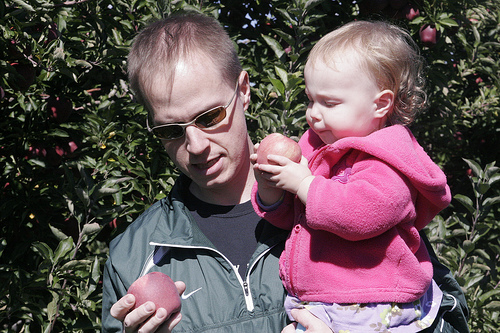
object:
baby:
[248, 22, 453, 333]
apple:
[253, 132, 304, 171]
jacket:
[241, 123, 454, 305]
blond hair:
[301, 21, 427, 128]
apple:
[124, 269, 182, 325]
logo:
[181, 285, 204, 301]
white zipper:
[233, 279, 260, 312]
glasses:
[140, 82, 237, 145]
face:
[140, 52, 245, 187]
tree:
[0, 0, 499, 333]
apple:
[50, 136, 79, 156]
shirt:
[101, 190, 468, 333]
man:
[89, 5, 466, 333]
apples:
[417, 23, 436, 43]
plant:
[438, 154, 499, 280]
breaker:
[109, 270, 184, 333]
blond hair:
[123, 9, 240, 100]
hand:
[255, 153, 310, 194]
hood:
[344, 118, 449, 231]